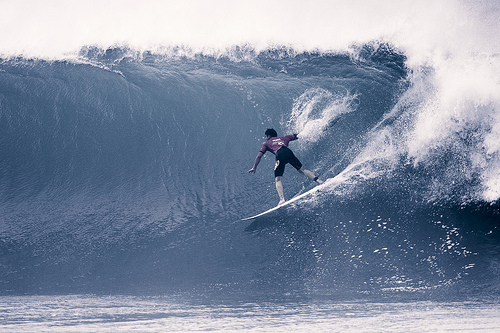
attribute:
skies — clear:
[29, 9, 306, 59]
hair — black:
[264, 127, 276, 137]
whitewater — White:
[404, 7, 498, 189]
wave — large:
[0, 12, 498, 326]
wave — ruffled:
[4, 34, 498, 303]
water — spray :
[112, 142, 227, 253]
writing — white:
[273, 136, 283, 144]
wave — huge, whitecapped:
[17, 25, 498, 159]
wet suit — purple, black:
[257, 136, 302, 172]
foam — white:
[19, 31, 498, 94]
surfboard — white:
[237, 163, 357, 221]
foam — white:
[291, 82, 360, 155]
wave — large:
[4, 37, 495, 234]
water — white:
[156, 282, 245, 329]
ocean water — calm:
[17, 293, 437, 324]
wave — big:
[2, 0, 499, 296]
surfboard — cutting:
[239, 177, 359, 216]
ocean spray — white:
[376, 39, 431, 141]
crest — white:
[8, 24, 485, 74]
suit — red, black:
[259, 130, 313, 188]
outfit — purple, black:
[252, 139, 313, 197]